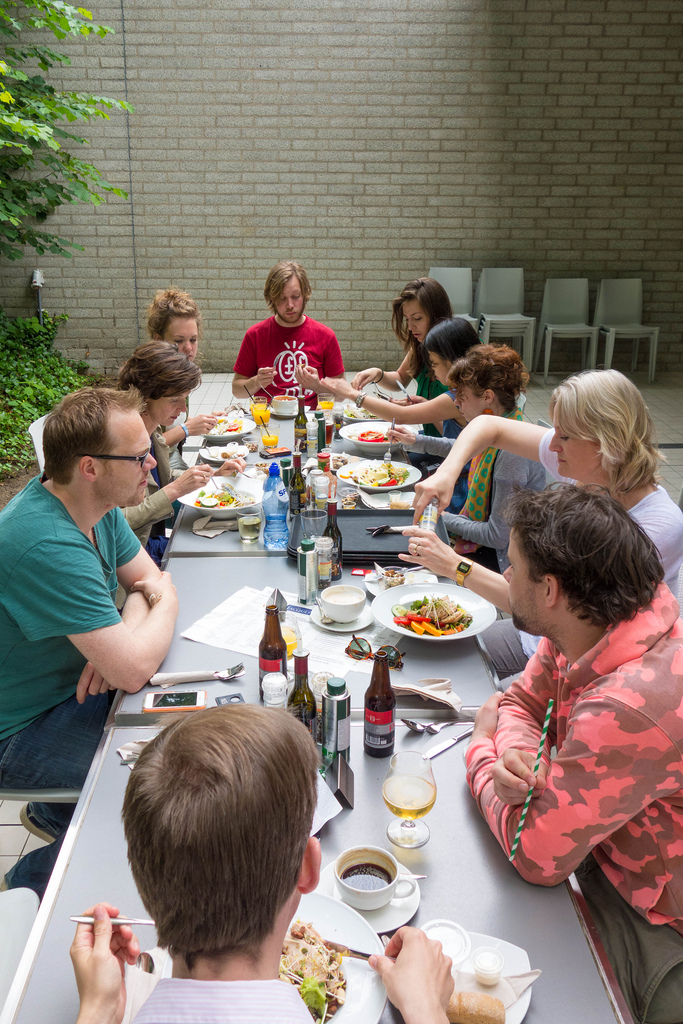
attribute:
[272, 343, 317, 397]
writing — white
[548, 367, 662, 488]
hair — blonde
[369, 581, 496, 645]
bowl — white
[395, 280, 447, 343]
hair — brown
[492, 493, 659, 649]
head — man's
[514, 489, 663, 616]
hair — brown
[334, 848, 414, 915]
cup — white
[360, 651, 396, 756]
bottle — amber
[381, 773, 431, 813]
liquid — yellow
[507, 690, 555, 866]
straw — green-and-white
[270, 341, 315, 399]
design — white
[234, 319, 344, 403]
shirt — red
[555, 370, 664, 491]
hair — shoulder-length, blonde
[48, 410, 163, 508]
face — man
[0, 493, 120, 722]
shirt — green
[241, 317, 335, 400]
shirt — red and white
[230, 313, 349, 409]
shirt — red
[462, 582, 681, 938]
jacket — peach colored, camo, coral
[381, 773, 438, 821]
wine — white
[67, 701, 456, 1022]
man — blonde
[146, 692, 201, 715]
case — peach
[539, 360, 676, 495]
hair — short, wavy, blonde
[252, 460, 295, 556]
bottle — water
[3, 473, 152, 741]
shirt — green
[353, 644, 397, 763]
bottle — brown, beer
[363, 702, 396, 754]
label — white, grey, red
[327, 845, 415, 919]
cup — white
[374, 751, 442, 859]
glass — wine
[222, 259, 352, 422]
man — bearded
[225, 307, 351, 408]
shirt — reddish, tee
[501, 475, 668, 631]
hair — brown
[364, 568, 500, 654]
plate — white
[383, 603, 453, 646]
dish — veggie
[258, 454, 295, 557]
bottle — blue, plastic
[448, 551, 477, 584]
watch — goldtone, digital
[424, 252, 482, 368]
chairs — white, patio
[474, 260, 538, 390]
chairs — white, patio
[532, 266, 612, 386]
chairs — white, patio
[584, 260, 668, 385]
chairs — white, patio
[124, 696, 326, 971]
hair — brown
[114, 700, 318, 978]
hair — brown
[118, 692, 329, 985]
hair — brown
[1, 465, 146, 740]
t-shirt — green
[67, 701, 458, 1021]
person — collared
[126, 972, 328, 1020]
shirt — white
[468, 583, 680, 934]
hoodie — orange, camo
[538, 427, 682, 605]
t-shirt — white